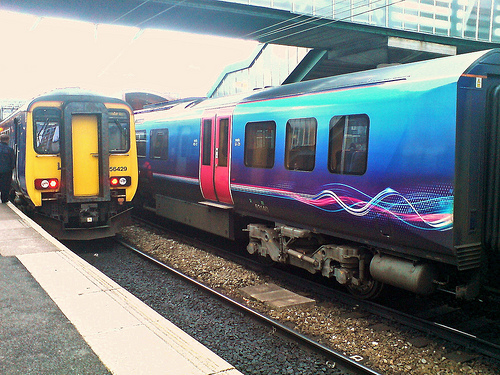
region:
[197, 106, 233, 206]
red doors on a train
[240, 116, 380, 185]
windows on the side of a train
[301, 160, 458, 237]
decorative painting on the side of a train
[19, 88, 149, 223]
yellow and black front of a train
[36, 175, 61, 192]
head lights on a train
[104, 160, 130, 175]
black numbers on a train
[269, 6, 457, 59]
walkway bridge over two trains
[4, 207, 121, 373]
cement train platform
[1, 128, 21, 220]
a passenger boarding a yellow train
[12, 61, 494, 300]
two trains passing at a station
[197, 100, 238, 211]
two door on side of train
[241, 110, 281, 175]
passengers window on train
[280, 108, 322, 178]
passengers window on train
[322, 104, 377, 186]
passengers window on train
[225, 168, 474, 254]
colorful paint design on side of train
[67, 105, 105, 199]
yellow door on back of train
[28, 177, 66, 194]
lights on back of train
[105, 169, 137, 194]
lights on back of train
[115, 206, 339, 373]
train tracks with gravel between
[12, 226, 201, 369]
cement sidewalk in train station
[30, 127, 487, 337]
two trains on tracks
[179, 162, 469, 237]
pink and blue wave on train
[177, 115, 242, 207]
pink doors on train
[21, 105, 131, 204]
yellow rear on train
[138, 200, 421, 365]
brown dirt between tracks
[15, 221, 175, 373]
light brown bricks on platform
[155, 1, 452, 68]
walkway is above train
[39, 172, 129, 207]
red headlights on train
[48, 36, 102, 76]
bright grey sky above trains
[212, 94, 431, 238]
blue wall on train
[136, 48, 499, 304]
purple and blue train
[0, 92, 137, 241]
yellow and black train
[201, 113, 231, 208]
pink doors on train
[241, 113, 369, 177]
glass windows on train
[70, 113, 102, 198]
yellow door on train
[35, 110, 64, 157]
glass window on train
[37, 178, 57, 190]
rear lights on train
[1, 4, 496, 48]
blue metal walking bridge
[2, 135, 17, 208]
person boarding yellow train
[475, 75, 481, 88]
number decal on train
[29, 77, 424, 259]
Train on the tracks.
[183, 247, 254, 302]
Gravel between the tracks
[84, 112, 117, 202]
The door of the train.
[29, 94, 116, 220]
The train is yellow in front.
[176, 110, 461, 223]
The train is blue ad red.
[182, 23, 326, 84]
Staircse at the train station.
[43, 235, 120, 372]
Walkway near the tracks.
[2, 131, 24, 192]
Person waiting for train.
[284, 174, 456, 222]
Design on the train.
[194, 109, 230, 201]
The doors is red.